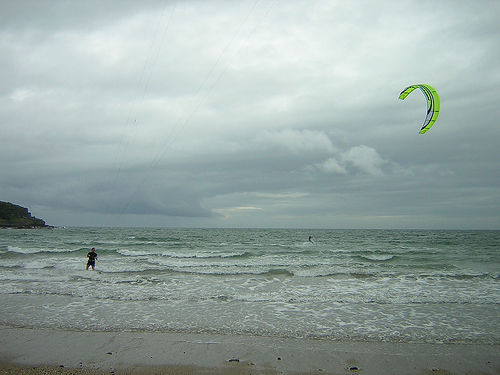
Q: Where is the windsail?
A: On the top right corner.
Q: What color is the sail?
A: Green.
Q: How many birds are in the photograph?
A: None.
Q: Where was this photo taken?
A: At the ocean.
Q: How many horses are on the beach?
A: Zero.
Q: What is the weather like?
A: Cloudy.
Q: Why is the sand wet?
A: From the ocean waves.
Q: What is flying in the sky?
A: Parachute.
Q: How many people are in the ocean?
A: Two.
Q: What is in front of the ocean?
A: The beach.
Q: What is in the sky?
A: Clouds.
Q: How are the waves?
A: Rolling.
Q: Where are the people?
A: The ocean.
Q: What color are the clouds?
A: Grey.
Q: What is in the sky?
A: Clouds.